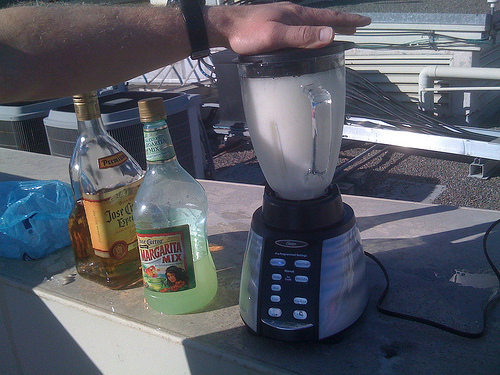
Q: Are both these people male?
A: No, they are both male and female.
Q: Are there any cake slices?
A: No, there are no cake slices.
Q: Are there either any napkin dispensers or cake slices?
A: No, there are no cake slices or napkin dispensers.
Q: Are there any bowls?
A: No, there are no bowls.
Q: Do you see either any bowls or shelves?
A: No, there are no bowls or shelves.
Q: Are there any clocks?
A: No, there are no clocks.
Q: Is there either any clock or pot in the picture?
A: No, there are no clocks or pots.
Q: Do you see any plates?
A: No, there are no plates.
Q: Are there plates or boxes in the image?
A: No, there are no plates or boxes.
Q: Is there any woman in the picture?
A: Yes, there is a woman.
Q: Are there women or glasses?
A: Yes, there is a woman.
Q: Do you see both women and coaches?
A: No, there is a woman but no coaches.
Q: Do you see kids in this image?
A: No, there are no kids.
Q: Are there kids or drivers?
A: No, there are no kids or drivers.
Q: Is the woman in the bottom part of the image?
A: Yes, the woman is in the bottom of the image.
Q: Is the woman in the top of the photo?
A: No, the woman is in the bottom of the image.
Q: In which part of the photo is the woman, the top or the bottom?
A: The woman is in the bottom of the image.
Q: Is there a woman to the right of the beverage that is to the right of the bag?
A: Yes, there is a woman to the right of the beverage.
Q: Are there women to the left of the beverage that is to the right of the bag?
A: No, the woman is to the right of the beverage.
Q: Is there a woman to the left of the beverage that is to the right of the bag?
A: No, the woman is to the right of the beverage.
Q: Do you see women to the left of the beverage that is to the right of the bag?
A: No, the woman is to the right of the beverage.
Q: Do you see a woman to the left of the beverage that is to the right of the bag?
A: No, the woman is to the right of the beverage.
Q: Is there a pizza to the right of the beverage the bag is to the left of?
A: No, there is a woman to the right of the beverage.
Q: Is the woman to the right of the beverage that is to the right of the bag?
A: Yes, the woman is to the right of the beverage.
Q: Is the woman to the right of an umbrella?
A: No, the woman is to the right of the beverage.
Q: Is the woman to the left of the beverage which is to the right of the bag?
A: No, the woman is to the right of the beverage.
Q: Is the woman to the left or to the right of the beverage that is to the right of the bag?
A: The woman is to the right of the beverage.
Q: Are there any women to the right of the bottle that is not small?
A: Yes, there is a woman to the right of the bottle.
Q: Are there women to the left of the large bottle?
A: No, the woman is to the right of the bottle.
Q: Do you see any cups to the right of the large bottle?
A: No, there is a woman to the right of the bottle.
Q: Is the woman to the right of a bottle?
A: Yes, the woman is to the right of a bottle.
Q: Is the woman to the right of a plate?
A: No, the woman is to the right of a bottle.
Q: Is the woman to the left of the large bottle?
A: No, the woman is to the right of the bottle.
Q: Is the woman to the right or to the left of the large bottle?
A: The woman is to the right of the bottle.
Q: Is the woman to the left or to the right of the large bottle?
A: The woman is to the right of the bottle.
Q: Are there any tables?
A: Yes, there is a table.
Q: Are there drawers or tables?
A: Yes, there is a table.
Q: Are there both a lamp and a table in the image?
A: No, there is a table but no lamps.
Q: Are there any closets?
A: No, there are no closets.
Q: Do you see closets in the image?
A: No, there are no closets.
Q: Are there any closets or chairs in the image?
A: No, there are no closets or chairs.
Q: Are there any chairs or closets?
A: No, there are no closets or chairs.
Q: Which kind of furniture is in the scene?
A: The furniture is a table.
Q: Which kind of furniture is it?
A: The piece of furniture is a table.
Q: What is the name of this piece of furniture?
A: This is a table.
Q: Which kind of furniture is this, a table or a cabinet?
A: This is a table.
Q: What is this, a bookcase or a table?
A: This is a table.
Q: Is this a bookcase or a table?
A: This is a table.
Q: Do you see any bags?
A: Yes, there is a bag.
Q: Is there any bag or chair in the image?
A: Yes, there is a bag.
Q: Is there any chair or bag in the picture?
A: Yes, there is a bag.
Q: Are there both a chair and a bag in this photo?
A: No, there is a bag but no chairs.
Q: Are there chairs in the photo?
A: No, there are no chairs.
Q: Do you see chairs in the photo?
A: No, there are no chairs.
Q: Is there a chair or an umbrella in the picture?
A: No, there are no chairs or umbrellas.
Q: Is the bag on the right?
A: No, the bag is on the left of the image.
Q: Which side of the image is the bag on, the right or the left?
A: The bag is on the left of the image.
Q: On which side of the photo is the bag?
A: The bag is on the left of the image.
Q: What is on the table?
A: The bag is on the table.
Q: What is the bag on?
A: The bag is on the table.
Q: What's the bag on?
A: The bag is on the table.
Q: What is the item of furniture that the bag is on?
A: The piece of furniture is a table.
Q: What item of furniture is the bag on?
A: The bag is on the table.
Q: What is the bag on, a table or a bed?
A: The bag is on a table.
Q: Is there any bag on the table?
A: Yes, there is a bag on the table.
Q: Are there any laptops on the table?
A: No, there is a bag on the table.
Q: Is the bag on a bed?
A: No, the bag is on a table.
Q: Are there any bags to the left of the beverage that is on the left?
A: Yes, there is a bag to the left of the beverage.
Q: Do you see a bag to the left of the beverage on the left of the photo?
A: Yes, there is a bag to the left of the beverage.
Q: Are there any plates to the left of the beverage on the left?
A: No, there is a bag to the left of the beverage.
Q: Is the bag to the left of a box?
A: No, the bag is to the left of the beverage.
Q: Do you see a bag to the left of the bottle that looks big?
A: Yes, there is a bag to the left of the bottle.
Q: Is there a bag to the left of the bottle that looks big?
A: Yes, there is a bag to the left of the bottle.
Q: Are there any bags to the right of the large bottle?
A: No, the bag is to the left of the bottle.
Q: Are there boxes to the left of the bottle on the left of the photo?
A: No, there is a bag to the left of the bottle.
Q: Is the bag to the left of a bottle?
A: Yes, the bag is to the left of a bottle.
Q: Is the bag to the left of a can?
A: No, the bag is to the left of a bottle.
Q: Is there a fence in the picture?
A: No, there are no fences.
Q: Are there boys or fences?
A: No, there are no fences or boys.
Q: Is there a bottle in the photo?
A: Yes, there is a bottle.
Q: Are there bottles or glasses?
A: Yes, there is a bottle.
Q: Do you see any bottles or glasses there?
A: Yes, there is a bottle.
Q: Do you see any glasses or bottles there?
A: Yes, there is a bottle.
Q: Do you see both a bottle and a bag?
A: Yes, there are both a bottle and a bag.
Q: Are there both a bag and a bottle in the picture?
A: Yes, there are both a bottle and a bag.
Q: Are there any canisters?
A: No, there are no canisters.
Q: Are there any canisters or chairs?
A: No, there are no canisters or chairs.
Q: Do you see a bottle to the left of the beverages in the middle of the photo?
A: Yes, there is a bottle to the left of the beverages.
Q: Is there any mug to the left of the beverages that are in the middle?
A: No, there is a bottle to the left of the beverages.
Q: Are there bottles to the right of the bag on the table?
A: Yes, there is a bottle to the right of the bag.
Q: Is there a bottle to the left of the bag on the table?
A: No, the bottle is to the right of the bag.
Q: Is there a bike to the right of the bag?
A: No, there is a bottle to the right of the bag.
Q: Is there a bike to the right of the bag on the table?
A: No, there is a bottle to the right of the bag.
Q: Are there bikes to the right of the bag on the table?
A: No, there is a bottle to the right of the bag.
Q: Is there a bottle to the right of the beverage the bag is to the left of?
A: Yes, there is a bottle to the right of the beverage.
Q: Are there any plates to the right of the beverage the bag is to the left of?
A: No, there is a bottle to the right of the beverage.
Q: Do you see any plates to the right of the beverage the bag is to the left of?
A: No, there is a bottle to the right of the beverage.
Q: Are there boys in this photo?
A: No, there are no boys.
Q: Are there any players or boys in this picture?
A: No, there are no boys or players.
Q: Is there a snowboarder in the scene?
A: No, there are no snowboarders.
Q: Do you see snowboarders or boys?
A: No, there are no snowboarders or boys.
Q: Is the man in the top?
A: Yes, the man is in the top of the image.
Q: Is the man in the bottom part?
A: No, the man is in the top of the image.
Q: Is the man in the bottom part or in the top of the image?
A: The man is in the top of the image.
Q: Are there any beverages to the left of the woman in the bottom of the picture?
A: Yes, there is a beverage to the left of the woman.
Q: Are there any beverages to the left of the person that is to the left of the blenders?
A: Yes, there is a beverage to the left of the woman.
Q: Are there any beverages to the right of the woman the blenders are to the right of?
A: No, the beverage is to the left of the woman.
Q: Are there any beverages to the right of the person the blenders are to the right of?
A: No, the beverage is to the left of the woman.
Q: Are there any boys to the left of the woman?
A: No, there is a beverage to the left of the woman.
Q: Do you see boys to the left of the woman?
A: No, there is a beverage to the left of the woman.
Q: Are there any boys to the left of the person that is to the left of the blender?
A: No, there is a beverage to the left of the woman.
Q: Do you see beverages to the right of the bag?
A: Yes, there is a beverage to the right of the bag.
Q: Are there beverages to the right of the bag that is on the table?
A: Yes, there is a beverage to the right of the bag.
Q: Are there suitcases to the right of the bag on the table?
A: No, there is a beverage to the right of the bag.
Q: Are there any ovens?
A: No, there are no ovens.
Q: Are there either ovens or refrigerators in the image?
A: No, there are no ovens or refrigerators.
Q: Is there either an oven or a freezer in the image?
A: No, there are no ovens or refrigerators.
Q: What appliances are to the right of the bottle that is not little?
A: The appliances are blenders.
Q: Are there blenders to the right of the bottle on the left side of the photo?
A: Yes, there are blenders to the right of the bottle.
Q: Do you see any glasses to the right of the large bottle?
A: No, there are blenders to the right of the bottle.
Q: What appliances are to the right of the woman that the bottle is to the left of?
A: The appliances are blenders.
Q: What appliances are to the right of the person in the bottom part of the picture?
A: The appliances are blenders.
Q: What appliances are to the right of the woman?
A: The appliances are blenders.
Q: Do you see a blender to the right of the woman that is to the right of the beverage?
A: Yes, there are blenders to the right of the woman.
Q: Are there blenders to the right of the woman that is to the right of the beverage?
A: Yes, there are blenders to the right of the woman.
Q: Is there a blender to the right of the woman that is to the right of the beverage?
A: Yes, there are blenders to the right of the woman.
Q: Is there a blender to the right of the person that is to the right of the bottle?
A: Yes, there are blenders to the right of the woman.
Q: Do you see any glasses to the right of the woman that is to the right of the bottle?
A: No, there are blenders to the right of the woman.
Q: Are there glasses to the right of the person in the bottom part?
A: No, there are blenders to the right of the woman.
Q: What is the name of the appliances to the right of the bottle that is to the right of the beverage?
A: The appliances are blenders.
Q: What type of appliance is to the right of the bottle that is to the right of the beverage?
A: The appliances are blenders.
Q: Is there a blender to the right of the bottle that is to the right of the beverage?
A: Yes, there are blenders to the right of the bottle.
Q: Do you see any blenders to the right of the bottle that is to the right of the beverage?
A: Yes, there are blenders to the right of the bottle.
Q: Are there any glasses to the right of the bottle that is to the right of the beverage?
A: No, there are blenders to the right of the bottle.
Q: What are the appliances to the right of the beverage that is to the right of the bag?
A: The appliances are blenders.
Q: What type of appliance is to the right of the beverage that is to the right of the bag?
A: The appliances are blenders.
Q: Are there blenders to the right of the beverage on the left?
A: Yes, there are blenders to the right of the beverage.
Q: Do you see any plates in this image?
A: No, there are no plates.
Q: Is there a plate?
A: No, there are no plates.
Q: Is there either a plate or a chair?
A: No, there are no plates or chairs.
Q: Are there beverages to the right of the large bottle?
A: Yes, there are beverages to the right of the bottle.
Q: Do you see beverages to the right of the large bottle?
A: Yes, there are beverages to the right of the bottle.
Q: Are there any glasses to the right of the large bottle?
A: No, there are beverages to the right of the bottle.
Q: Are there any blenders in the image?
A: Yes, there is a blender.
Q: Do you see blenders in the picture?
A: Yes, there is a blender.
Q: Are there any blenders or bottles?
A: Yes, there is a blender.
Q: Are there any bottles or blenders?
A: Yes, there is a blender.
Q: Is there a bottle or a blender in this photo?
A: Yes, there is a blender.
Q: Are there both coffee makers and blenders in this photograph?
A: No, there is a blender but no coffee makers.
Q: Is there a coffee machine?
A: No, there are no coffee makers.